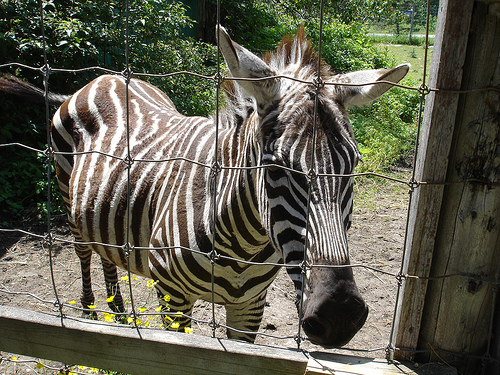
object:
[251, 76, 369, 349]
head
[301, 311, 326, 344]
nostril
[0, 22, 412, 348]
animal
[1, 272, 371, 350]
dirt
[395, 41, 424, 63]
grass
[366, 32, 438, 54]
ground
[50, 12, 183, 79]
leaves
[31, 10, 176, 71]
trees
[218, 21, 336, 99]
hair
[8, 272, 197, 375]
flowers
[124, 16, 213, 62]
foliage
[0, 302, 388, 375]
post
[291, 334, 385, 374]
shadow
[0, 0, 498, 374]
fence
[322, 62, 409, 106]
ears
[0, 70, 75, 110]
tail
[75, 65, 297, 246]
stripes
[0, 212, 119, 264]
grass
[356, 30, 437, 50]
road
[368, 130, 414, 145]
grass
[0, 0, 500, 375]
fence board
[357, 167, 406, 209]
grass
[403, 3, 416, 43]
sign post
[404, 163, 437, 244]
window edge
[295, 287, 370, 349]
nose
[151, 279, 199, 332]
leg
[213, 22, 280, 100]
ear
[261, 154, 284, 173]
eye